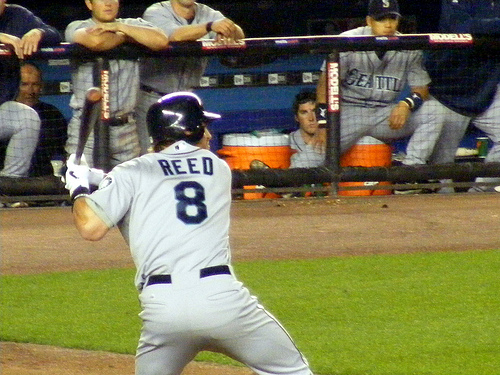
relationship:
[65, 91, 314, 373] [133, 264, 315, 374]
player wearing pants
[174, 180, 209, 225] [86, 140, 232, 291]
number on jersey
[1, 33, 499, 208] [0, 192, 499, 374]
fence beside field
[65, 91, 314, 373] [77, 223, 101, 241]
player has a elbow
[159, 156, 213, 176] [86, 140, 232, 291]
writting on jersey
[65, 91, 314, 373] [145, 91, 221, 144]
player wearing a helmet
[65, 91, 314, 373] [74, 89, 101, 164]
player holding bat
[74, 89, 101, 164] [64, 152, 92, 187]
bat in hands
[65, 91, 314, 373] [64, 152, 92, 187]
player has hands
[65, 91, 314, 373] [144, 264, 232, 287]
player wearing a belt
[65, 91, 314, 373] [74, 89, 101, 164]
player swinging bat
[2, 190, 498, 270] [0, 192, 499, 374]
strip on field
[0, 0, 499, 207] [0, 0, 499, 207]
players in dugout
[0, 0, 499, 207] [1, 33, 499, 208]
players hanging on fence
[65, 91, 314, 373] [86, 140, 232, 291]
player wearing a jersey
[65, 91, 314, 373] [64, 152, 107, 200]
player wearing gloves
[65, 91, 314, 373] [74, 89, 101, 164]
player has a bat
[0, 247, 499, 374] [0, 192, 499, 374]
grass on field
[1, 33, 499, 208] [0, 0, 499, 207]
fence in front of dugout